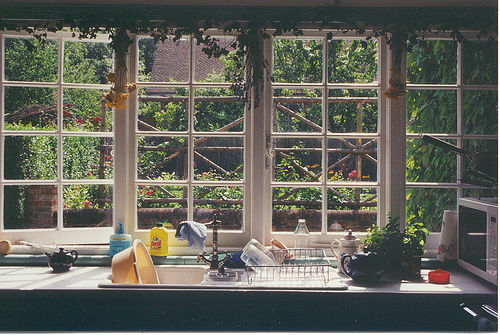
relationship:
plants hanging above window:
[0, 10, 498, 112] [270, 33, 401, 250]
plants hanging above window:
[0, 10, 498, 112] [139, 35, 245, 225]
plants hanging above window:
[82, 10, 164, 110] [139, 35, 245, 225]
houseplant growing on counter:
[362, 217, 431, 281] [347, 285, 464, 302]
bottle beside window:
[293, 218, 310, 257] [275, 32, 381, 237]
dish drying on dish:
[245, 247, 331, 284] [245, 247, 331, 284]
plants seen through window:
[4, 38, 495, 231] [7, 27, 498, 237]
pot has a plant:
[353, 254, 433, 278] [351, 210, 433, 253]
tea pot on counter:
[45, 247, 78, 272] [0, 243, 499, 295]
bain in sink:
[107, 236, 161, 282] [99, 264, 209, 287]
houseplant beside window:
[362, 217, 431, 281] [7, 27, 498, 237]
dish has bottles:
[245, 247, 331, 284] [234, 235, 349, 282]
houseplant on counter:
[362, 217, 431, 281] [0, 255, 497, 307]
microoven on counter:
[445, 182, 497, 305] [1, 259, 499, 293]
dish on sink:
[245, 247, 331, 284] [123, 201, 264, 309]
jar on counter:
[287, 220, 315, 251] [3, 268, 61, 297]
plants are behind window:
[9, 42, 496, 222] [7, 27, 498, 237]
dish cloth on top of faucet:
[178, 221, 207, 250] [168, 218, 226, 273]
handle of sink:
[196, 252, 210, 264] [100, 263, 207, 286]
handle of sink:
[221, 250, 229, 265] [100, 263, 207, 286]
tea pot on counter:
[45, 247, 78, 272] [2, 263, 484, 298]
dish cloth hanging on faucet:
[174, 218, 214, 253] [168, 208, 225, 272]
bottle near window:
[258, 182, 318, 284] [261, 34, 418, 269]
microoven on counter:
[457, 196, 499, 286] [2, 267, 475, 293]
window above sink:
[276, 35, 371, 232] [127, 261, 331, 291]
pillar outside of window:
[23, 185, 58, 228] [1, 27, 113, 244]